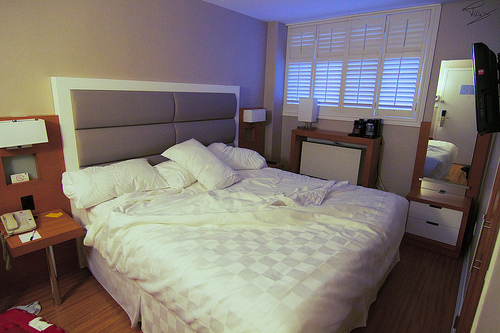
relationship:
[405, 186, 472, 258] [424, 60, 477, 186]
stand has a mirror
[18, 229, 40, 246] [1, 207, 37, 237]
paper beside phone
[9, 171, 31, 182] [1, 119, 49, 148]
card under lamp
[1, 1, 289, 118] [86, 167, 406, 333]
wall in front of bed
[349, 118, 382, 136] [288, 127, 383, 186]
coffe maker on table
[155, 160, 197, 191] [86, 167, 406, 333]
pillow on bed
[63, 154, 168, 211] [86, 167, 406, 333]
pillow on bed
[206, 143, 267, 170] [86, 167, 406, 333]
pillow on bed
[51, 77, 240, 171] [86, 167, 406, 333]
headboard on bed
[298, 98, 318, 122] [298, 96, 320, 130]
shade on lamp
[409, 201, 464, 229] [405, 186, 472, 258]
drawer on stand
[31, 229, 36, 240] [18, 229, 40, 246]
pen on paper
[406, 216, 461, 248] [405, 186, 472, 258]
drawer on stand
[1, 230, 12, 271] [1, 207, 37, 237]
cord on phone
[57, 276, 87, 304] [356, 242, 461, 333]
shadow on floor